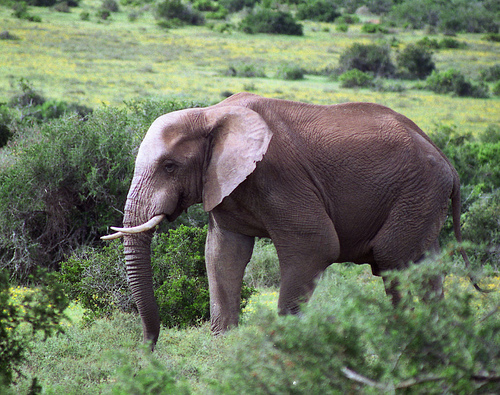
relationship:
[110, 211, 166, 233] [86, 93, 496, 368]
tusk of an elephant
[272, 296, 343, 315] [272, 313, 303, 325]
ankle of a feet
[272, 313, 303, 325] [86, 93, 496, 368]
feet of an elephant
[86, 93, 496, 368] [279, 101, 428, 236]
elephant has skin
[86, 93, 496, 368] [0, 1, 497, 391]
elephant standing between brush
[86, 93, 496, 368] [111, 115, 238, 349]
elephant has head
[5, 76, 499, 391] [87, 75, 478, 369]
brushes are next to elephant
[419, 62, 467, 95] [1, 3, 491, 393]
bushes are on field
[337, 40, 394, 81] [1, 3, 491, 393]
bushes are on field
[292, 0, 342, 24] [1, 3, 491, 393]
bushes are on field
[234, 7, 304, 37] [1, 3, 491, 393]
bushes are on field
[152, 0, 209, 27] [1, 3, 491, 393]
bushes are on field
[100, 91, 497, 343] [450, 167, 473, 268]
elephant has tail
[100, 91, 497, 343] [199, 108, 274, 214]
elephant has ear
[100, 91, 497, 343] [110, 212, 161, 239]
elephant has tusk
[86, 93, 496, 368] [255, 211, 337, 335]
elephant has leg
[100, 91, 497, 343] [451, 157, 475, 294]
elephant has tail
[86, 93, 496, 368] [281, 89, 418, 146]
elephant has back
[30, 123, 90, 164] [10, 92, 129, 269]
leaves on tree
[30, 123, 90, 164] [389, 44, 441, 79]
leaves on tree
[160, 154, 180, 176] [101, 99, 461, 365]
eye on elephant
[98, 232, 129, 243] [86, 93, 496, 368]
right tusk on elephant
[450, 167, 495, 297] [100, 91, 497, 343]
tail on elephant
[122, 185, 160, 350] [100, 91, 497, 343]
elephant trunk on elephant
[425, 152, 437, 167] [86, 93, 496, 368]
bump on elephant